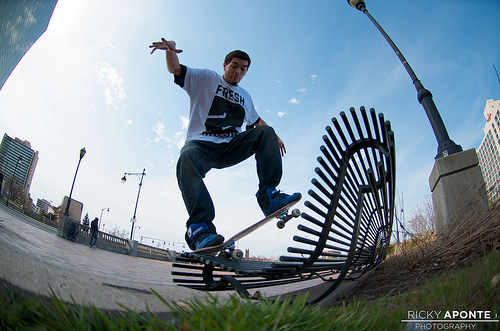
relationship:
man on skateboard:
[146, 37, 303, 249] [188, 192, 303, 261]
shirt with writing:
[165, 40, 292, 167] [217, 80, 247, 100]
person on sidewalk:
[87, 214, 102, 246] [9, 195, 388, 328]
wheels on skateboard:
[270, 208, 302, 228] [175, 190, 305, 268]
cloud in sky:
[97, 60, 131, 108] [0, 3, 499, 258]